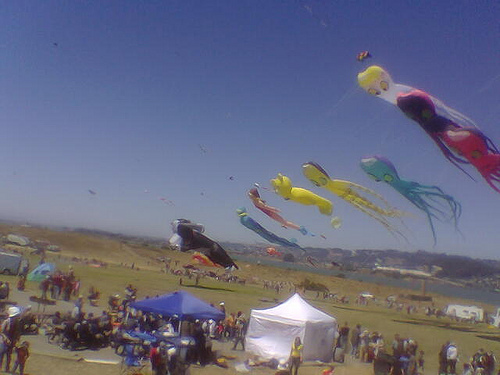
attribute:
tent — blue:
[127, 288, 226, 338]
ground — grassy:
[0, 222, 500, 373]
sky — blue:
[1, 0, 498, 265]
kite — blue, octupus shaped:
[359, 154, 462, 243]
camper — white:
[446, 304, 487, 328]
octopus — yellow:
[284, 157, 386, 241]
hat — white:
[0, 304, 21, 318]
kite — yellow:
[268, 172, 360, 229]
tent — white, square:
[244, 292, 337, 364]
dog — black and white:
[162, 213, 245, 275]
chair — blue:
[117, 342, 147, 370]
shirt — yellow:
[288, 342, 302, 357]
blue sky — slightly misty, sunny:
[0, 2, 498, 260]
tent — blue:
[129, 290, 246, 320]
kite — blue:
[345, 157, 427, 216]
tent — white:
[242, 292, 338, 374]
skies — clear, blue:
[83, 42, 207, 140]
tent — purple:
[132, 290, 226, 321]